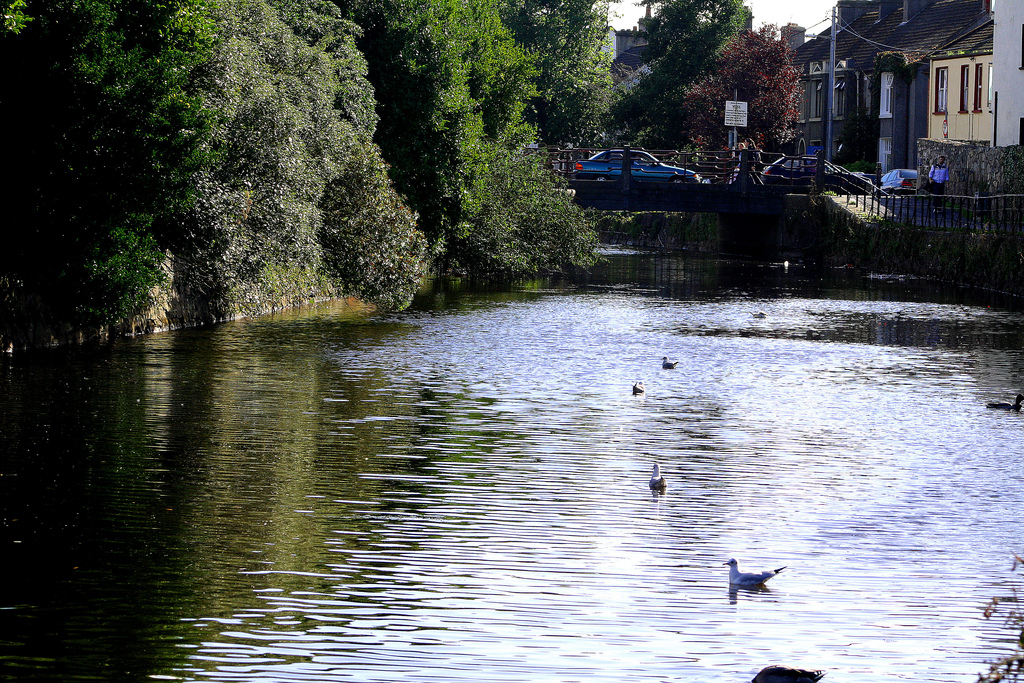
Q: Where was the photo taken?
A: A river.